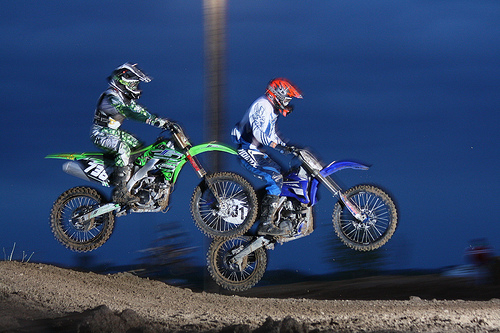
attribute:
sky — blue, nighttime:
[0, 1, 500, 271]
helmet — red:
[265, 76, 304, 118]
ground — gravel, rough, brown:
[0, 257, 498, 332]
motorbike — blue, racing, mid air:
[206, 144, 400, 293]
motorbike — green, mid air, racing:
[44, 119, 258, 253]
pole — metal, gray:
[200, 0, 229, 297]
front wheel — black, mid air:
[330, 181, 400, 254]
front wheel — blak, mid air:
[189, 169, 259, 242]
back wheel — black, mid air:
[205, 230, 266, 292]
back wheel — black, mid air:
[49, 187, 115, 254]